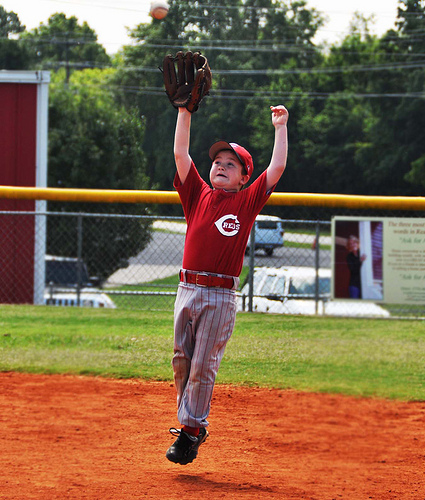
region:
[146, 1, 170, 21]
a baseball in mid-air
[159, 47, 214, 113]
a dark brown baseball mitt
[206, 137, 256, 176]
a red baseball cap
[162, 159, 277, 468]
a uniform for the Chicago Reds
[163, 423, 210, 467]
a pair of baseball cleats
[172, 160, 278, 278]
a red t-shirt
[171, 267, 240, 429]
dark gray pants with red pinstripes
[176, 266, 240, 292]
a red belt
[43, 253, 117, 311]
a silver jeep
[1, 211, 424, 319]
a chainlink fence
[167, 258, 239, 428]
Gray with red striped pants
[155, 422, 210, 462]
Black shoes on a boy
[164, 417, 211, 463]
Red socks with black shoes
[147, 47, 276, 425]
A boy playing baseball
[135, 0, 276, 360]
A boy catching a ball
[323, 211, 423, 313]
A sign on the fence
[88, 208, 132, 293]
A chain linked fence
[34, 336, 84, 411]
Green grass and sand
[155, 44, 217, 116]
A brown baseball glove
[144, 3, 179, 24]
A white baseball in the air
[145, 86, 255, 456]
A kid playing baseball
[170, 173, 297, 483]
A kid playing baseball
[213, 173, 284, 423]
A kid playing baseball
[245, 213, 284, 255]
Car on the road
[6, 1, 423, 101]
Electric wires in the sky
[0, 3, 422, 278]
Trees outside of the baseball court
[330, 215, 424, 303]
Advertisement on the fence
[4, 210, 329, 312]
Metal fence surround the baseball court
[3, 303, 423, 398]
Grass between the fence and the baseball court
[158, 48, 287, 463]
Boy jumping in the air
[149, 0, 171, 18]
Baseball in the air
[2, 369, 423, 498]
Brown baseball court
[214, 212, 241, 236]
Logo on the boy's shirt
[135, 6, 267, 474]
boy about to catch a ball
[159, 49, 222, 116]
boy wearing a catcher's mitt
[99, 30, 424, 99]
a telephone pole's wires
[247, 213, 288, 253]
back of a white van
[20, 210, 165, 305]
a metal fence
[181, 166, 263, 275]
boy wearing a red shirt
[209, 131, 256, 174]
boy wearing a cap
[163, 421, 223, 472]
black shoes and red socks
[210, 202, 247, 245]
white logo on a shirt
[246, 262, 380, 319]
a white car